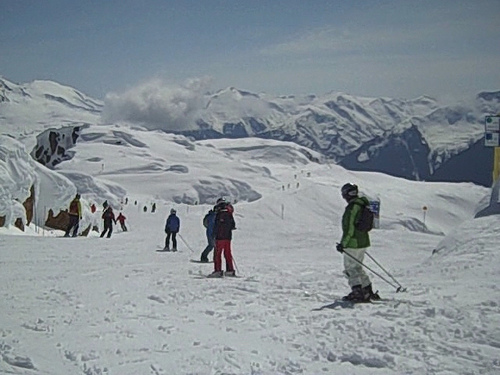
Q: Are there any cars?
A: No, there are no cars.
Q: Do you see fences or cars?
A: No, there are no cars or fences.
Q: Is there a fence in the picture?
A: No, there are no fences.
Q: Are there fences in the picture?
A: No, there are no fences.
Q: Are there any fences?
A: No, there are no fences.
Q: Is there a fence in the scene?
A: No, there are no fences.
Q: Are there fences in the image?
A: No, there are no fences.